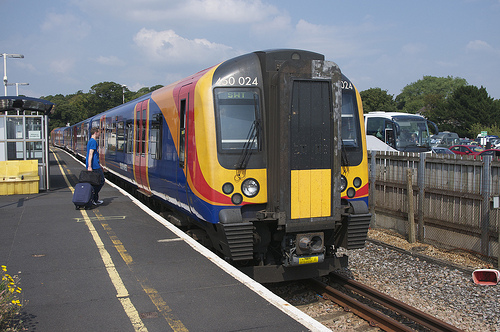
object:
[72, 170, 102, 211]
suitcase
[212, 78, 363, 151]
windscreen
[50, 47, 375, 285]
commuter train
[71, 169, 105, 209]
bags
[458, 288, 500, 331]
rocks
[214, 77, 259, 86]
number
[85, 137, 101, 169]
shirt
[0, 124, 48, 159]
wall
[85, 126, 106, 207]
man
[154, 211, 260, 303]
line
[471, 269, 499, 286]
cone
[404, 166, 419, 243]
wooden post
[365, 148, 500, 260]
fence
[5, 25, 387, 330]
station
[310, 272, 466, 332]
railway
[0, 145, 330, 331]
sidewalk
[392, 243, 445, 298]
rocks